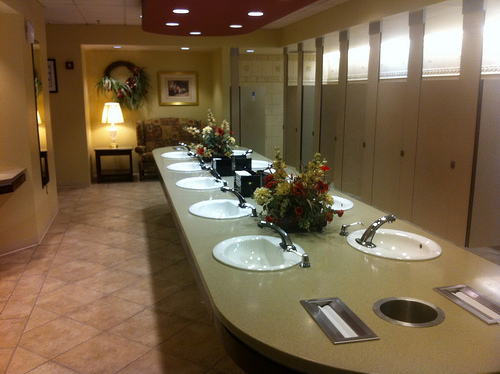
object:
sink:
[212, 233, 308, 272]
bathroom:
[0, 0, 500, 373]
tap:
[253, 219, 299, 250]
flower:
[264, 179, 278, 190]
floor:
[0, 179, 247, 373]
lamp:
[97, 101, 127, 148]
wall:
[44, 24, 92, 189]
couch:
[133, 116, 205, 181]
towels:
[233, 169, 253, 176]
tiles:
[103, 303, 194, 348]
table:
[91, 147, 138, 183]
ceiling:
[37, 0, 350, 40]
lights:
[168, 9, 194, 16]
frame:
[156, 70, 201, 107]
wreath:
[93, 59, 155, 112]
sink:
[186, 197, 254, 220]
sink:
[172, 174, 227, 191]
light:
[244, 10, 266, 19]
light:
[186, 30, 205, 36]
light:
[228, 24, 246, 30]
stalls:
[340, 82, 367, 201]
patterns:
[157, 124, 183, 139]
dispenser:
[298, 294, 381, 345]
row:
[161, 149, 306, 283]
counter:
[150, 143, 500, 373]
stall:
[264, 85, 284, 160]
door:
[237, 84, 266, 157]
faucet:
[353, 213, 398, 249]